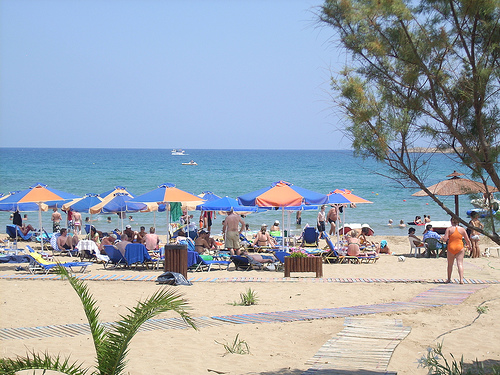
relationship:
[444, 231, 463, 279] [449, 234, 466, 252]
woman in orange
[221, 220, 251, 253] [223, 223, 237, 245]
man in shorts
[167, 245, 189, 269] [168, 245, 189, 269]
wooden garbage wooden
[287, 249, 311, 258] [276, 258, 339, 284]
plant in trash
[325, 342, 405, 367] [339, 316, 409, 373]
wood on sidewalk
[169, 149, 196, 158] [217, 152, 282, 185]
white boat water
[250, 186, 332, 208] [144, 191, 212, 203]
orange blue umbrella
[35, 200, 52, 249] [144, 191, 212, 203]
wooden pole umbrella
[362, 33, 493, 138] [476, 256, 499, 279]
tree in ground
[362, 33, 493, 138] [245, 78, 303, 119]
tree on right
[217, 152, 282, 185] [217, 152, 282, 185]
water in water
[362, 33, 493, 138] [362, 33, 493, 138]
tree green tree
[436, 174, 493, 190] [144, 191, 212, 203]
brown shade umbrella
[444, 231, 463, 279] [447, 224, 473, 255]
woman in suit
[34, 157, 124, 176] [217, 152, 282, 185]
ocean in water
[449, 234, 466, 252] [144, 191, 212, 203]
orange blue umbrella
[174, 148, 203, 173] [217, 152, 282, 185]
boat in water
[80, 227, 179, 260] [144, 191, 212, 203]
people under umbrella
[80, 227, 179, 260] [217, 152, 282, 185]
people in water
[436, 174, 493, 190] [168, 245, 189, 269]
brown trash wooden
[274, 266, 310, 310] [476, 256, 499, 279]
sand on ground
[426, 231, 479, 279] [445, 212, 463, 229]
woman has hair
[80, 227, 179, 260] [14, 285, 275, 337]
people at beach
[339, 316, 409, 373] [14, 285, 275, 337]
sidewalk on beach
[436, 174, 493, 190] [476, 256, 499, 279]
brown umbrella ground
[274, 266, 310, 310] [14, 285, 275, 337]
sand on beach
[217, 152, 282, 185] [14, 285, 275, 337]
water by beach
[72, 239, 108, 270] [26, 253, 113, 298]
towel on chair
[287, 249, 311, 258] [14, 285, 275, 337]
plant in beach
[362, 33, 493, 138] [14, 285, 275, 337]
tree on beach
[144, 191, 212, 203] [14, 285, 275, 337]
umbrella at beach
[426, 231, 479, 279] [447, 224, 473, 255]
woman in suit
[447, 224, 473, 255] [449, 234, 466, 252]
suit suit orange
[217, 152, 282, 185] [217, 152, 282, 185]
water sea water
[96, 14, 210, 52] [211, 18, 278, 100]
blue above sky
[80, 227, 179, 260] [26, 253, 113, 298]
people in chair